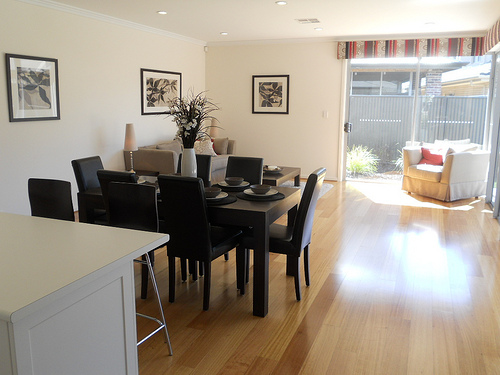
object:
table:
[73, 170, 303, 318]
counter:
[1, 208, 168, 373]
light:
[331, 220, 478, 309]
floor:
[49, 171, 499, 375]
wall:
[204, 36, 346, 187]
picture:
[251, 73, 291, 115]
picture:
[138, 69, 184, 116]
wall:
[0, 1, 206, 219]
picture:
[4, 52, 63, 122]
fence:
[348, 93, 487, 179]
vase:
[180, 148, 198, 181]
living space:
[0, 0, 499, 375]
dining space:
[0, 0, 333, 375]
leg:
[145, 253, 178, 354]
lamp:
[122, 120, 140, 171]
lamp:
[210, 116, 219, 127]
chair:
[238, 167, 330, 302]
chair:
[154, 174, 246, 312]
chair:
[223, 155, 263, 280]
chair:
[102, 181, 161, 298]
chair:
[70, 153, 123, 228]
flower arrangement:
[159, 91, 219, 154]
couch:
[129, 139, 238, 183]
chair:
[400, 136, 491, 203]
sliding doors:
[342, 60, 419, 182]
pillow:
[418, 147, 444, 165]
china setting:
[242, 183, 280, 197]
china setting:
[216, 175, 249, 189]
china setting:
[199, 185, 229, 200]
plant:
[345, 143, 378, 177]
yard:
[346, 138, 483, 182]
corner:
[399, 172, 479, 201]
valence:
[331, 22, 500, 62]